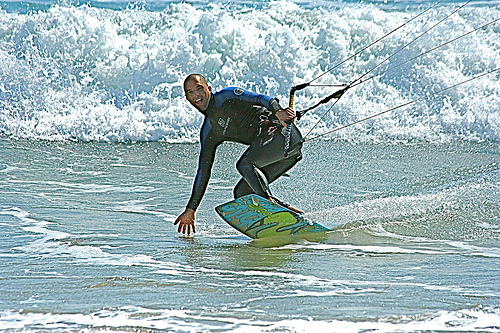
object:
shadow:
[185, 241, 294, 269]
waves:
[15, 214, 364, 286]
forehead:
[184, 76, 201, 89]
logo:
[234, 88, 244, 95]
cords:
[349, 16, 499, 88]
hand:
[275, 108, 294, 127]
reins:
[249, 116, 283, 145]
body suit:
[187, 87, 304, 209]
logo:
[218, 118, 225, 127]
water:
[0, 0, 496, 327]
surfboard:
[215, 194, 332, 240]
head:
[184, 73, 212, 110]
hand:
[174, 211, 196, 234]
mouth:
[195, 99, 202, 103]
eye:
[196, 88, 201, 91]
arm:
[185, 130, 222, 211]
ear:
[207, 86, 211, 91]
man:
[174, 74, 301, 232]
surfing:
[177, 71, 335, 237]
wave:
[4, 3, 494, 141]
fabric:
[214, 87, 281, 111]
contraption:
[285, 83, 348, 152]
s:
[256, 211, 296, 238]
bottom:
[217, 195, 331, 240]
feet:
[287, 207, 302, 214]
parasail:
[285, 0, 499, 153]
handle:
[284, 89, 295, 150]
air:
[1, 1, 500, 333]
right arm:
[215, 87, 282, 112]